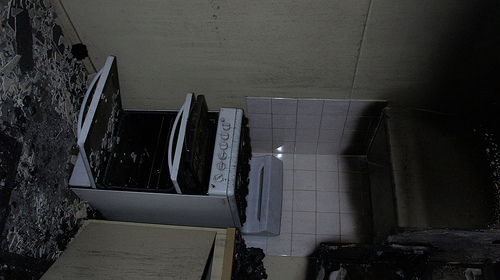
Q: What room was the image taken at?
A: It was taken at the kitchen.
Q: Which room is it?
A: It is a kitchen.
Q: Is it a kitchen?
A: Yes, it is a kitchen.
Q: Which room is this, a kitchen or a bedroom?
A: It is a kitchen.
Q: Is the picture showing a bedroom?
A: No, the picture is showing a kitchen.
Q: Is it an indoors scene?
A: Yes, it is indoors.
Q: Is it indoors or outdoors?
A: It is indoors.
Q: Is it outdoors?
A: No, it is indoors.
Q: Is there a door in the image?
A: Yes, there are doors.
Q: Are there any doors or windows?
A: Yes, there are doors.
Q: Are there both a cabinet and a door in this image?
A: Yes, there are both a door and a cabinet.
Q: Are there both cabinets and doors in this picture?
A: Yes, there are both doors and a cabinet.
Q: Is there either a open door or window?
A: Yes, there are open doors.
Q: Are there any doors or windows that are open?
A: Yes, the doors are open.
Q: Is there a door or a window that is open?
A: Yes, the doors are open.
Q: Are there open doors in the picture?
A: Yes, there are open doors.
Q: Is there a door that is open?
A: Yes, there are doors that are open.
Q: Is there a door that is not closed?
A: Yes, there are open doors.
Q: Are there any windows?
A: No, there are no windows.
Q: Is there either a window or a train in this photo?
A: No, there are no windows or trains.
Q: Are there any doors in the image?
A: Yes, there is a door.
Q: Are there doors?
A: Yes, there is a door.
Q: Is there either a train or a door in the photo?
A: Yes, there is a door.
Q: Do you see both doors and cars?
A: No, there is a door but no cars.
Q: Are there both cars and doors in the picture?
A: No, there is a door but no cars.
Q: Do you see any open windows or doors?
A: Yes, there is an open door.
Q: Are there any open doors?
A: Yes, there is an open door.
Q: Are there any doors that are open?
A: Yes, there is a door that is open.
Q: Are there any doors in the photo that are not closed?
A: Yes, there is a open door.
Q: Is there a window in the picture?
A: No, there are no windows.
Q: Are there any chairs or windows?
A: No, there are no windows or chairs.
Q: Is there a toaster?
A: No, there are no toasters.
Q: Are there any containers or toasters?
A: No, there are no toasters or containers.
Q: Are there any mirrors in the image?
A: No, there are no mirrors.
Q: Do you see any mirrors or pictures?
A: No, there are no mirrors or pictures.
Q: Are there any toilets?
A: No, there are no toilets.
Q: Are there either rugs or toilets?
A: No, there are no toilets or rugs.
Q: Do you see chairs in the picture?
A: No, there are no chairs.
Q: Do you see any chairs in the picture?
A: No, there are no chairs.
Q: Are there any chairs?
A: No, there are no chairs.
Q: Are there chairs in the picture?
A: No, there are no chairs.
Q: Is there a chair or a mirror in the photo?
A: No, there are no chairs or mirrors.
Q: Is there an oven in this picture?
A: Yes, there is an oven.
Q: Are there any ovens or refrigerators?
A: Yes, there is an oven.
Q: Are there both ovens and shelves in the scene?
A: No, there is an oven but no shelves.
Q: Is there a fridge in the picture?
A: No, there are no refrigerators.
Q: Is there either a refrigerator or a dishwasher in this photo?
A: No, there are no refrigerators or dishwashers.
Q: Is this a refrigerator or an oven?
A: This is an oven.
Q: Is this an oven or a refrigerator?
A: This is an oven.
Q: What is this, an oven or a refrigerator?
A: This is an oven.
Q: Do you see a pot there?
A: No, there are no pots.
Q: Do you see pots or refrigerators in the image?
A: No, there are no pots or refrigerators.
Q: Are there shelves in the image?
A: No, there are no shelves.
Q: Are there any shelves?
A: No, there are no shelves.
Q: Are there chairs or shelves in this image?
A: No, there are no shelves or chairs.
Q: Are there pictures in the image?
A: No, there are no pictures.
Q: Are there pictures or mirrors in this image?
A: No, there are no pictures or mirrors.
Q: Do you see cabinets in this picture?
A: Yes, there is a cabinet.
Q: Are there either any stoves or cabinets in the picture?
A: Yes, there is a cabinet.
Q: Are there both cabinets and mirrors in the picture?
A: No, there is a cabinet but no mirrors.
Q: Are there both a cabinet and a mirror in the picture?
A: No, there is a cabinet but no mirrors.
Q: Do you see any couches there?
A: No, there are no couches.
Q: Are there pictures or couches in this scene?
A: No, there are no couches or pictures.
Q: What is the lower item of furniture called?
A: The piece of furniture is a cabinet.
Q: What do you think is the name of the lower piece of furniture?
A: The piece of furniture is a cabinet.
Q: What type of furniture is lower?
A: The furniture is a cabinet.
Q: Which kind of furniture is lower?
A: The furniture is a cabinet.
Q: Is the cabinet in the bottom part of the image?
A: Yes, the cabinet is in the bottom of the image.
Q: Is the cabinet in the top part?
A: No, the cabinet is in the bottom of the image.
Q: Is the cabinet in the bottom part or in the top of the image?
A: The cabinet is in the bottom of the image.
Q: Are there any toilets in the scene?
A: No, there are no toilets.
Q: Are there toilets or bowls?
A: No, there are no toilets or bowls.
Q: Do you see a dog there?
A: No, there are no dogs.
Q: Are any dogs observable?
A: No, there are no dogs.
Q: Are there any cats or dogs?
A: No, there are no dogs or cats.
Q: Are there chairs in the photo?
A: No, there are no chairs.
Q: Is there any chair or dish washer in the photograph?
A: No, there are no chairs or dishwashers.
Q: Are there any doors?
A: Yes, there is a door.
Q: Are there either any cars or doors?
A: Yes, there is a door.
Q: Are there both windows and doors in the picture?
A: No, there is a door but no windows.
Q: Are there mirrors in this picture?
A: No, there are no mirrors.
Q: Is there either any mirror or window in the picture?
A: No, there are no mirrors or windows.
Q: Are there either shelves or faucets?
A: No, there are no shelves or faucets.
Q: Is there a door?
A: Yes, there is a door.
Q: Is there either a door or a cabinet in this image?
A: Yes, there is a door.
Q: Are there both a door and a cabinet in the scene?
A: Yes, there are both a door and a cabinet.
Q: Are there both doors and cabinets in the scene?
A: Yes, there are both a door and a cabinet.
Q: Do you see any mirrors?
A: No, there are no mirrors.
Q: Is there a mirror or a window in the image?
A: No, there are no mirrors or windows.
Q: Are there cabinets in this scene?
A: Yes, there is a cabinet.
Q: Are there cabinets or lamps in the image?
A: Yes, there is a cabinet.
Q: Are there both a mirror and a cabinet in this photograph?
A: No, there is a cabinet but no mirrors.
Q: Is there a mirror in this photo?
A: No, there are no mirrors.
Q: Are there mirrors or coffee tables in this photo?
A: No, there are no mirrors or coffee tables.